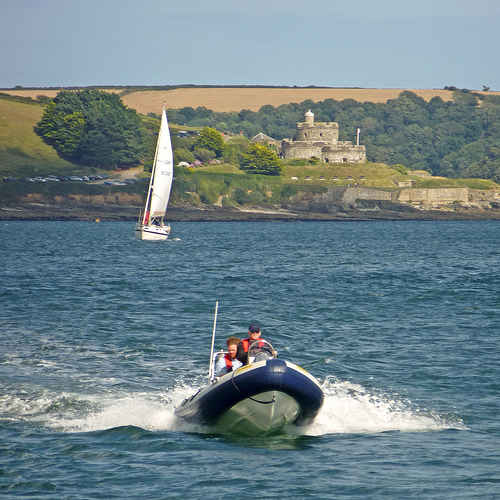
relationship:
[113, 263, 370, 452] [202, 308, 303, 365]
boat with people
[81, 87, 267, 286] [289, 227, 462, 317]
sailboat on water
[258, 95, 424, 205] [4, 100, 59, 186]
castle on hills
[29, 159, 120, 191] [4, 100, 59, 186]
cars on hills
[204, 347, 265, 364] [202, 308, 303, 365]
vests on people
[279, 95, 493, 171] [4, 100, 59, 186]
trees cover hills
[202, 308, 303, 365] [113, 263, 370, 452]
people in boat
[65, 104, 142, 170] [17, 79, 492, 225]
bush in background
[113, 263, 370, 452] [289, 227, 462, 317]
boat in water